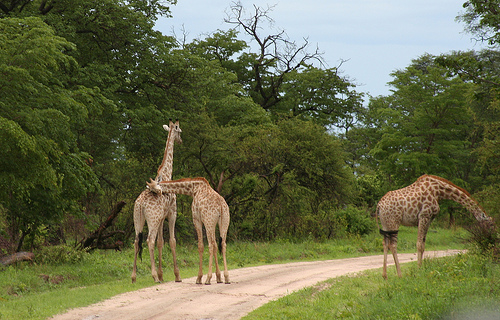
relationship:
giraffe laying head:
[145, 177, 231, 286] [147, 179, 162, 196]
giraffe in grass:
[129, 122, 184, 286] [1, 228, 384, 317]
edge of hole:
[430, 282, 497, 319] [438, 293, 498, 319]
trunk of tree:
[1, 250, 33, 268] [1, 202, 126, 269]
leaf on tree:
[171, 0, 175, 5] [117, 0, 181, 27]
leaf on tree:
[171, 0, 175, 5] [1, 202, 126, 269]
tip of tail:
[137, 232, 143, 260] [136, 199, 147, 263]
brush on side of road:
[58, 210, 125, 261] [49, 247, 472, 320]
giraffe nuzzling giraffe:
[145, 177, 231, 286] [129, 122, 184, 286]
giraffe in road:
[145, 177, 231, 286] [49, 247, 472, 320]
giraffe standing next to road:
[129, 122, 184, 286] [49, 247, 472, 320]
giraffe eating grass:
[376, 174, 500, 279] [242, 245, 499, 319]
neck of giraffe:
[156, 134, 176, 180] [129, 122, 184, 286]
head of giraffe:
[477, 215, 498, 244] [376, 174, 500, 279]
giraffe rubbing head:
[145, 177, 231, 286] [147, 179, 162, 196]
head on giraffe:
[147, 179, 162, 196] [129, 122, 184, 286]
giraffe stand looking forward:
[129, 122, 184, 286] [185, 2, 500, 245]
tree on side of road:
[1, 202, 126, 269] [49, 247, 472, 320]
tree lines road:
[200, 0, 347, 118] [49, 247, 472, 320]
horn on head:
[149, 178, 157, 185] [147, 179, 162, 196]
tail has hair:
[136, 199, 147, 263] [135, 231, 145, 262]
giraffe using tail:
[376, 174, 500, 279] [375, 203, 402, 246]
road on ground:
[49, 247, 472, 320] [2, 220, 499, 319]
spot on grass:
[34, 270, 63, 289] [1, 228, 384, 317]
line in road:
[273, 266, 340, 291] [49, 247, 472, 320]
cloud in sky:
[401, 0, 475, 36] [152, 1, 497, 107]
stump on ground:
[2, 246, 41, 267] [2, 220, 499, 319]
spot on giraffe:
[199, 274, 204, 280] [145, 177, 231, 286]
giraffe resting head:
[145, 177, 231, 286] [147, 179, 162, 196]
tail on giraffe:
[136, 199, 147, 263] [129, 122, 184, 286]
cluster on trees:
[0, 17, 77, 82] [1, 4, 128, 251]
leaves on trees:
[14, 29, 94, 182] [1, 4, 128, 251]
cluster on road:
[131, 119, 498, 288] [49, 247, 472, 320]